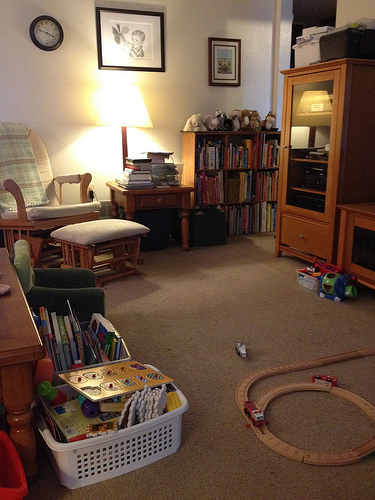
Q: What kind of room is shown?
A: Living room.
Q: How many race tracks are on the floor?
A: One.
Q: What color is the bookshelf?
A: Brown.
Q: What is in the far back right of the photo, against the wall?
A: Bookcase.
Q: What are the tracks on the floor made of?
A: Wood.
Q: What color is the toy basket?
A: White.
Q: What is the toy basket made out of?
A: Plastic.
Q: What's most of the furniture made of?
A: Wood.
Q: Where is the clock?
A: Wall.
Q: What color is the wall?
A: White.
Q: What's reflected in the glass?
A: Lamp.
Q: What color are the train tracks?
A: Tan.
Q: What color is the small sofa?
A: Green.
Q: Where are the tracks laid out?
A: On the floor.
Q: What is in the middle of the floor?
A: A track.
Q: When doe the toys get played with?
A: Play time.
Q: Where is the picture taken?
A: Living room.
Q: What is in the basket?
A: Puzzles.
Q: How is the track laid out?
A: In a circle.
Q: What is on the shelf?
A: Books.